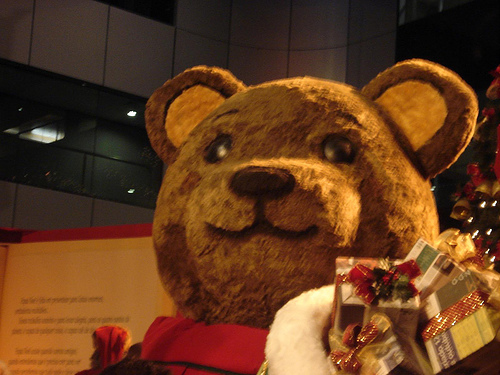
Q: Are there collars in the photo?
A: Yes, there is a collar.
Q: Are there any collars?
A: Yes, there is a collar.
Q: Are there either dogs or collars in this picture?
A: Yes, there is a collar.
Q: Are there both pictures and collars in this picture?
A: No, there is a collar but no pictures.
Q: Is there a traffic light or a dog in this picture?
A: No, there are no dogs or traffic lights.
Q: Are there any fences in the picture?
A: No, there are no fences.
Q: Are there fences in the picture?
A: No, there are no fences.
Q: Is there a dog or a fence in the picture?
A: No, there are no fences or dogs.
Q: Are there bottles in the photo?
A: No, there are no bottles.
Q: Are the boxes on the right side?
A: Yes, the boxes are on the right of the image.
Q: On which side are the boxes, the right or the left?
A: The boxes are on the right of the image.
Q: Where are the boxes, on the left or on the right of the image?
A: The boxes are on the right of the image.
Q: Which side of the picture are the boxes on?
A: The boxes are on the right of the image.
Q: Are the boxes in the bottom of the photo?
A: Yes, the boxes are in the bottom of the image.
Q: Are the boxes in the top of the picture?
A: No, the boxes are in the bottom of the image.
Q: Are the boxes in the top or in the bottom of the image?
A: The boxes are in the bottom of the image.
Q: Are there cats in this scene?
A: No, there are no cats.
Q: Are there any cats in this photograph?
A: No, there are no cats.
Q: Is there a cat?
A: No, there are no cats.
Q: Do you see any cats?
A: No, there are no cats.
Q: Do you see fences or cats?
A: No, there are no cats or fences.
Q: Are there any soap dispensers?
A: No, there are no soap dispensers.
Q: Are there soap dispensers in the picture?
A: No, there are no soap dispensers.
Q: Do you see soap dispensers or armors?
A: No, there are no soap dispensers or armors.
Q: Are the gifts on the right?
A: Yes, the gifts are on the right of the image.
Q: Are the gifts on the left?
A: No, the gifts are on the right of the image.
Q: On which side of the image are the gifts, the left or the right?
A: The gifts are on the right of the image.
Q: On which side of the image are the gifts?
A: The gifts are on the right of the image.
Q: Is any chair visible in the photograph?
A: No, there are no chairs.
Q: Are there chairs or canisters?
A: No, there are no chairs or canisters.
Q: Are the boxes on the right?
A: Yes, the boxes are on the right of the image.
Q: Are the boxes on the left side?
A: No, the boxes are on the right of the image.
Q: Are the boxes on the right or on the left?
A: The boxes are on the right of the image.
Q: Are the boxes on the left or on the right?
A: The boxes are on the right of the image.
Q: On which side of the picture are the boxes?
A: The boxes are on the right of the image.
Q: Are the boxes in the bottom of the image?
A: Yes, the boxes are in the bottom of the image.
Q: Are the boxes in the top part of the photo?
A: No, the boxes are in the bottom of the image.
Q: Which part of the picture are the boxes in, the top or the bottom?
A: The boxes are in the bottom of the image.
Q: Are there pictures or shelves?
A: No, there are no pictures or shelves.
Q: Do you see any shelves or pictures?
A: No, there are no pictures or shelves.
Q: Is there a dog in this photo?
A: No, there are no dogs.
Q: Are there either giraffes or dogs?
A: No, there are no dogs or giraffes.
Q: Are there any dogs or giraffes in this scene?
A: No, there are no dogs or giraffes.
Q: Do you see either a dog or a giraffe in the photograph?
A: No, there are no dogs or giraffes.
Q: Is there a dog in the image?
A: No, there are no dogs.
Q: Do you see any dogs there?
A: No, there are no dogs.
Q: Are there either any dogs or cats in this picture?
A: No, there are no dogs or cats.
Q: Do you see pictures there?
A: No, there are no pictures.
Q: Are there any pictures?
A: No, there are no pictures.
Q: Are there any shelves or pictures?
A: No, there are no pictures or shelves.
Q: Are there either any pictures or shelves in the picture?
A: No, there are no pictures or shelves.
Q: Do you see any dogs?
A: No, there are no dogs.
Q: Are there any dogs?
A: No, there are no dogs.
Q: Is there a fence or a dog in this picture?
A: No, there are no dogs or fences.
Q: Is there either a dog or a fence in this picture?
A: No, there are no dogs or fences.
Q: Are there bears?
A: Yes, there is a bear.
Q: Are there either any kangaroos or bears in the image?
A: Yes, there is a bear.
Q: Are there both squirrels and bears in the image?
A: No, there is a bear but no squirrels.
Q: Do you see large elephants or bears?
A: Yes, there is a large bear.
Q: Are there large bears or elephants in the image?
A: Yes, there is a large bear.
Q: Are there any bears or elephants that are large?
A: Yes, the bear is large.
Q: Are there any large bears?
A: Yes, there is a large bear.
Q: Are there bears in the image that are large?
A: Yes, there is a bear that is large.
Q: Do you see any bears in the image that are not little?
A: Yes, there is a large bear.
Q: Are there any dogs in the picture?
A: No, there are no dogs.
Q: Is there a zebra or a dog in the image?
A: No, there are no dogs or zebras.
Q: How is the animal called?
A: The animal is a bear.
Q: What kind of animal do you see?
A: The animal is a bear.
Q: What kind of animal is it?
A: The animal is a bear.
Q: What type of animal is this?
A: This is a bear.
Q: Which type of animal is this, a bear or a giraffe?
A: This is a bear.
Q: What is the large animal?
A: The animal is a bear.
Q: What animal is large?
A: The animal is a bear.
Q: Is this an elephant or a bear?
A: This is a bear.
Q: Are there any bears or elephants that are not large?
A: No, there is a bear but it is large.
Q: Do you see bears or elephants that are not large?
A: No, there is a bear but it is large.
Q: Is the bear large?
A: Yes, the bear is large.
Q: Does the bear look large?
A: Yes, the bear is large.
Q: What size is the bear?
A: The bear is large.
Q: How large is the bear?
A: The bear is large.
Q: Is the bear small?
A: No, the bear is large.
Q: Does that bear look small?
A: No, the bear is large.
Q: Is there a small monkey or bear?
A: No, there is a bear but it is large.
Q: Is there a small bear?
A: No, there is a bear but it is large.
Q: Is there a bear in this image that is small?
A: No, there is a bear but it is large.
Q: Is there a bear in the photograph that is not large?
A: No, there is a bear but it is large.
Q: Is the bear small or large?
A: The bear is large.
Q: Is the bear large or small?
A: The bear is large.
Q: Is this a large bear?
A: Yes, this is a large bear.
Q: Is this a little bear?
A: No, this is a large bear.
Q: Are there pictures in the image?
A: No, there are no pictures.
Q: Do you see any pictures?
A: No, there are no pictures.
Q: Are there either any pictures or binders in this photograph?
A: No, there are no pictures or binders.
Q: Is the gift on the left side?
A: No, the gift is on the right of the image.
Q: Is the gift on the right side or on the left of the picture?
A: The gift is on the right of the image.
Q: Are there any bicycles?
A: No, there are no bicycles.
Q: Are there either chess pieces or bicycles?
A: No, there are no bicycles or chess pieces.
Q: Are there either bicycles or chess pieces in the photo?
A: No, there are no bicycles or chess pieces.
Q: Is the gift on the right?
A: Yes, the gift is on the right of the image.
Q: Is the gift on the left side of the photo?
A: No, the gift is on the right of the image.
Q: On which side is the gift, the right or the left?
A: The gift is on the right of the image.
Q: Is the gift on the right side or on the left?
A: The gift is on the right of the image.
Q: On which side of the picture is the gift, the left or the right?
A: The gift is on the right of the image.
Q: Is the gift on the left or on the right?
A: The gift is on the right of the image.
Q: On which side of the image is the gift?
A: The gift is on the right of the image.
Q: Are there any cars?
A: No, there are no cars.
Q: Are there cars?
A: No, there are no cars.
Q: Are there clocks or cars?
A: No, there are no cars or clocks.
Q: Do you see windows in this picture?
A: Yes, there are windows.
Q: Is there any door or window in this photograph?
A: Yes, there are windows.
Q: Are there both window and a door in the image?
A: No, there are windows but no doors.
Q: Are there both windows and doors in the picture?
A: No, there are windows but no doors.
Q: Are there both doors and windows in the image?
A: No, there are windows but no doors.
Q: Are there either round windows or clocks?
A: Yes, there are round windows.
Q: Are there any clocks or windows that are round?
A: Yes, the windows are round.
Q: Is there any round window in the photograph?
A: Yes, there are round windows.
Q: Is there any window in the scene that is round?
A: Yes, there are windows that are round.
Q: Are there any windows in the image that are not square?
A: Yes, there are round windows.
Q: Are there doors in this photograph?
A: No, there are no doors.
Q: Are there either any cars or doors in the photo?
A: No, there are no doors or cars.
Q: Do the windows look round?
A: Yes, the windows are round.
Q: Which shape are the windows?
A: The windows are round.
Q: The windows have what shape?
A: The windows are round.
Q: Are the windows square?
A: No, the windows are round.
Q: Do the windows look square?
A: No, the windows are round.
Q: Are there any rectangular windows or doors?
A: No, there are windows but they are round.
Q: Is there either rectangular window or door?
A: No, there are windows but they are round.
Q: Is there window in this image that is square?
A: No, there are windows but they are round.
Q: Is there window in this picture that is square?
A: No, there are windows but they are round.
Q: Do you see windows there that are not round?
A: No, there are windows but they are round.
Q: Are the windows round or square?
A: The windows are round.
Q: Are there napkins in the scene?
A: No, there are no napkins.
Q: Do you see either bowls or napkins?
A: No, there are no napkins or bowls.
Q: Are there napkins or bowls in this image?
A: No, there are no napkins or bowls.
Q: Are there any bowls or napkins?
A: No, there are no napkins or bowls.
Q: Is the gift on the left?
A: No, the gift is on the right of the image.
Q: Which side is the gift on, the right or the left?
A: The gift is on the right of the image.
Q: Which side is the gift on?
A: The gift is on the right of the image.